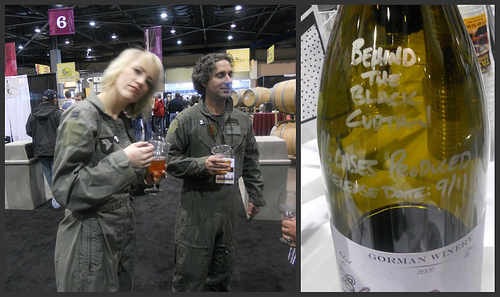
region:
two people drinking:
[40, 50, 280, 290]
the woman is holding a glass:
[117, 129, 172, 201]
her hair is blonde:
[94, 43, 169, 123]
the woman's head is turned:
[45, 35, 181, 294]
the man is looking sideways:
[167, 53, 268, 290]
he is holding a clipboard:
[230, 150, 270, 224]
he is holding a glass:
[192, 142, 238, 182]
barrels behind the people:
[230, 76, 307, 151]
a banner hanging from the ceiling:
[142, 17, 167, 68]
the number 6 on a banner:
[46, 0, 83, 41]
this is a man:
[176, 47, 257, 268]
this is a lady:
[77, 55, 154, 280]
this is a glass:
[151, 135, 171, 193]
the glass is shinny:
[153, 141, 171, 153]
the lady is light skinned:
[106, 88, 126, 103]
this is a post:
[49, 8, 76, 33]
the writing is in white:
[53, 15, 68, 32]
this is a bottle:
[325, 56, 470, 273]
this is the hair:
[193, 62, 206, 74]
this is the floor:
[6, 210, 26, 293]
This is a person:
[160, 34, 280, 294]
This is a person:
[42, 35, 170, 295]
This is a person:
[27, 85, 68, 205]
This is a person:
[151, 90, 166, 141]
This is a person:
[168, 88, 183, 125]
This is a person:
[58, 81, 74, 111]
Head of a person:
[32, 83, 61, 107]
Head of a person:
[101, 37, 180, 124]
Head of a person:
[189, 40, 254, 117]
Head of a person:
[170, 90, 185, 101]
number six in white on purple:
[43, 4, 88, 39]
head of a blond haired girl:
[97, 38, 171, 118]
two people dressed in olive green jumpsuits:
[51, 38, 275, 288]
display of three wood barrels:
[240, 76, 299, 149]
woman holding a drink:
[55, 41, 176, 288]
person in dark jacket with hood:
[25, 81, 65, 193]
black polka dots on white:
[288, 16, 333, 126]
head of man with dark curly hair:
[182, 43, 247, 105]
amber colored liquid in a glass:
[138, 129, 176, 199]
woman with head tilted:
[77, 34, 172, 141]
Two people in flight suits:
[70, 46, 243, 188]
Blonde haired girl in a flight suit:
[77, 19, 164, 204]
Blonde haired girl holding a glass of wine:
[91, 44, 172, 197]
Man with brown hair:
[183, 32, 251, 180]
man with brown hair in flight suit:
[183, 39, 253, 209]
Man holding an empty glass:
[186, 37, 248, 191]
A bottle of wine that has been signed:
[316, 17, 463, 261]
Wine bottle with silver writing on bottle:
[328, 32, 470, 205]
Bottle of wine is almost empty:
[293, 133, 464, 284]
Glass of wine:
[133, 129, 171, 196]